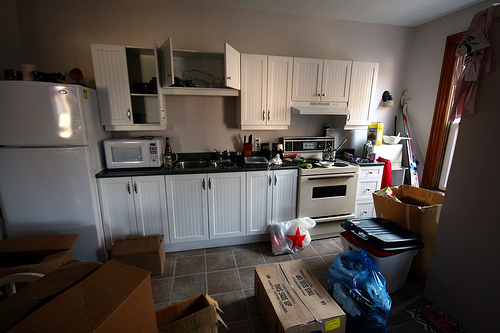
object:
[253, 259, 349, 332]
box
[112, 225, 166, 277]
box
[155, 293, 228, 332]
box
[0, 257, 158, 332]
box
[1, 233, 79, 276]
box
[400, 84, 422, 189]
skiis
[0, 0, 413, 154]
wall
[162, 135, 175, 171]
bottle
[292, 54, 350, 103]
cupboard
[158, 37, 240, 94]
cupboard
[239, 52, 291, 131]
cupboard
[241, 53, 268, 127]
door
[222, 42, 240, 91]
door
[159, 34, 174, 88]
door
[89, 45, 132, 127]
door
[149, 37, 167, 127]
door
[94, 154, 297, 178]
counter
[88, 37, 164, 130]
cupboard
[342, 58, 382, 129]
cupboard door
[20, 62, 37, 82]
stuff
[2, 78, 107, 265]
fridge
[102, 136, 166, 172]
microwave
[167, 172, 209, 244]
doors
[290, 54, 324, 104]
doors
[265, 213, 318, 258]
plastic bag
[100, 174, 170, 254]
cupboard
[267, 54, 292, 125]
door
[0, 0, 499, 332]
kitchen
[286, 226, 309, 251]
star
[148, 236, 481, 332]
ground